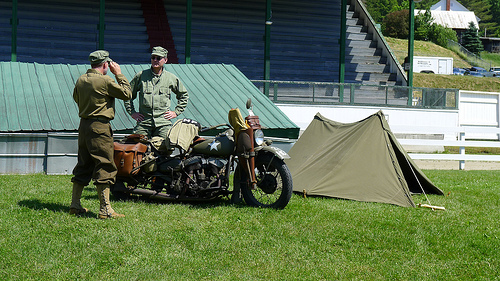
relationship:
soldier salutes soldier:
[69, 49, 134, 220] [123, 43, 189, 139]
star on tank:
[207, 139, 219, 151] [190, 135, 236, 155]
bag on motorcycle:
[112, 140, 150, 179] [106, 97, 292, 212]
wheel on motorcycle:
[238, 149, 293, 211] [106, 97, 292, 212]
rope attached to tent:
[384, 114, 436, 211] [275, 108, 445, 211]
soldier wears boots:
[69, 49, 134, 220] [69, 180, 125, 220]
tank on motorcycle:
[190, 135, 236, 155] [106, 97, 292, 212]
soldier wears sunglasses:
[123, 43, 189, 139] [150, 55, 165, 61]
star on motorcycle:
[207, 139, 219, 151] [106, 97, 292, 212]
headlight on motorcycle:
[251, 127, 265, 146] [106, 97, 292, 212]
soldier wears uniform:
[123, 43, 189, 139] [125, 67, 188, 140]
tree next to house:
[459, 21, 484, 57] [413, 8, 481, 48]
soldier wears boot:
[69, 49, 134, 220] [68, 181, 93, 215]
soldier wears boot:
[69, 49, 134, 220] [98, 185, 125, 221]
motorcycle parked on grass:
[106, 97, 292, 212] [1, 167, 499, 280]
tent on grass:
[275, 108, 445, 211] [1, 167, 499, 280]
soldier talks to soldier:
[69, 49, 134, 220] [123, 43, 189, 139]